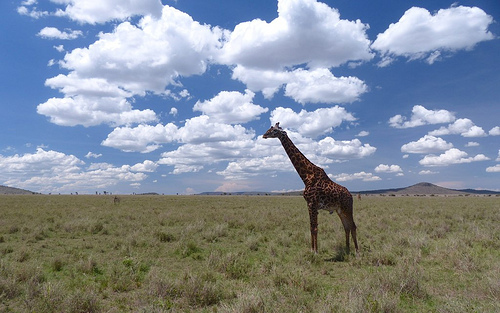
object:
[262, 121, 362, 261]
giraffe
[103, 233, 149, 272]
plains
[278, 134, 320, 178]
neck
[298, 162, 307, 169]
spots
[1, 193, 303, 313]
tall grass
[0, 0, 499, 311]
grazing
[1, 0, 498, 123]
blue skies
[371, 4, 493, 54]
white clouds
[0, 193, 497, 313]
grassy plains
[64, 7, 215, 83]
clouds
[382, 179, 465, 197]
hill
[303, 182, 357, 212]
large abdomen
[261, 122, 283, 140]
giraffes head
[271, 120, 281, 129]
horns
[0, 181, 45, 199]
hill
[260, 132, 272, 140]
large mouth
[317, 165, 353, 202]
back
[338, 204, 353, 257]
long legs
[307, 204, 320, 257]
long legs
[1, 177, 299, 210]
horizon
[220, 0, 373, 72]
puffy clouds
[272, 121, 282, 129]
two horns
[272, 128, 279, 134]
two ears